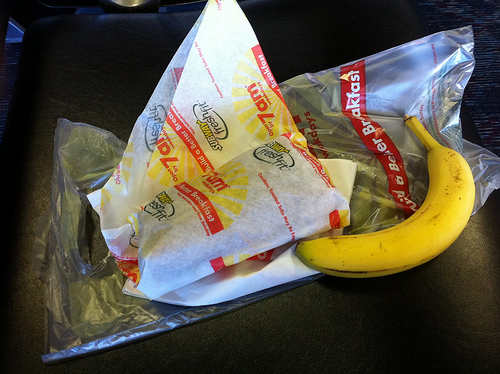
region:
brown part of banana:
[316, 232, 380, 248]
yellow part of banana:
[351, 242, 437, 270]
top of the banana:
[380, 102, 475, 182]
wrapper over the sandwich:
[132, 128, 299, 237]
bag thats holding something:
[28, 260, 224, 370]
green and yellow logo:
[188, 115, 246, 165]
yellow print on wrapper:
[189, 167, 269, 229]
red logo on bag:
[330, 89, 424, 239]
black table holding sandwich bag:
[270, 296, 440, 366]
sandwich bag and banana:
[63, 86, 493, 311]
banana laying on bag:
[306, 107, 489, 279]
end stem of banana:
[398, 112, 440, 146]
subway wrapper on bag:
[76, 107, 292, 257]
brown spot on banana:
[371, 238, 386, 253]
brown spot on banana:
[421, 212, 445, 228]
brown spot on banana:
[455, 194, 464, 204]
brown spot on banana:
[451, 171, 463, 185]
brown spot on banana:
[338, 260, 350, 268]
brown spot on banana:
[306, 252, 318, 269]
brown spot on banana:
[326, 233, 346, 248]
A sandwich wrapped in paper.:
[111, 123, 324, 270]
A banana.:
[321, 110, 476, 287]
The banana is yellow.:
[309, 124, 476, 296]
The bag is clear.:
[42, 45, 473, 350]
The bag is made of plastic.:
[43, 45, 444, 347]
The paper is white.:
[118, 57, 330, 262]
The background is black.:
[328, 300, 480, 366]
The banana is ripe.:
[283, 79, 475, 293]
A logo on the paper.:
[241, 130, 311, 173]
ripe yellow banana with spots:
[276, 90, 483, 290]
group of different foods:
[11, 36, 490, 368]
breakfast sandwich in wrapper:
[56, 33, 363, 315]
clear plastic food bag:
[18, 50, 494, 360]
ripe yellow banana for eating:
[279, 100, 484, 308]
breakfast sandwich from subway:
[13, 35, 486, 364]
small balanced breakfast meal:
[10, 2, 489, 362]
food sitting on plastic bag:
[26, 3, 496, 365]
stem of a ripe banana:
[387, 99, 472, 172]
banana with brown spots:
[410, 141, 484, 233]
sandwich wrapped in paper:
[140, 143, 336, 282]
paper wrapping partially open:
[147, 18, 281, 153]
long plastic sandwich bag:
[44, 37, 470, 335]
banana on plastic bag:
[314, 117, 468, 281]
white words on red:
[344, 62, 419, 203]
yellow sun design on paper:
[187, 157, 248, 230]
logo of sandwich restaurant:
[191, 115, 226, 156]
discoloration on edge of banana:
[323, 258, 373, 280]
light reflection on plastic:
[65, 286, 118, 331]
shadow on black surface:
[316, 276, 410, 307]